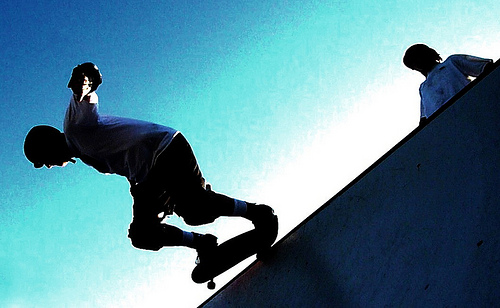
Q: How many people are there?
A: Two.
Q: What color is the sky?
A: Blue.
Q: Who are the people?
A: Men.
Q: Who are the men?
A: Skateboarders.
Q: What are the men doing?
A: Skating.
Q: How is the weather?
A: Warm.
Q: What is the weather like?
A: Sunny.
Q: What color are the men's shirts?
A: White.